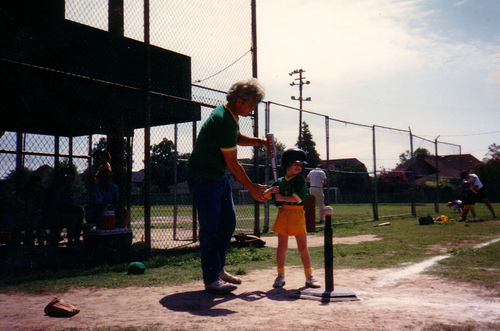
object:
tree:
[395, 146, 453, 167]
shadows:
[158, 276, 320, 317]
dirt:
[0, 265, 499, 330]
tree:
[293, 120, 323, 167]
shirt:
[186, 102, 240, 182]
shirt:
[307, 167, 328, 188]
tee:
[287, 206, 362, 304]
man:
[185, 77, 278, 292]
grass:
[0, 203, 499, 330]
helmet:
[281, 148, 309, 170]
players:
[0, 151, 130, 244]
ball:
[322, 205, 334, 215]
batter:
[262, 133, 321, 289]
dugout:
[0, 0, 204, 290]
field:
[0, 201, 500, 331]